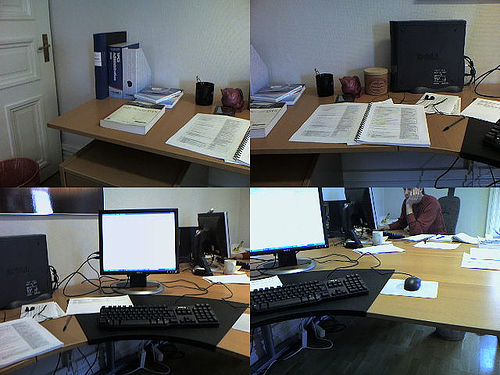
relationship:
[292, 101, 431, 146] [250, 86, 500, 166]
book on table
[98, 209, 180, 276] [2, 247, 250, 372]
monitor on desk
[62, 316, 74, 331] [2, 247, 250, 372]
pen on desk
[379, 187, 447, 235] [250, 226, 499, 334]
man sitting at desk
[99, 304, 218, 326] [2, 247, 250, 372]
keyboard on top of desk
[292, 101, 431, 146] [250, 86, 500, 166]
book on top of table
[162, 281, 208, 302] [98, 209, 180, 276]
wire surrounds monitor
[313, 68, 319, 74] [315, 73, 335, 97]
pencil inside holder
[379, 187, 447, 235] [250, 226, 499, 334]
man behind desk